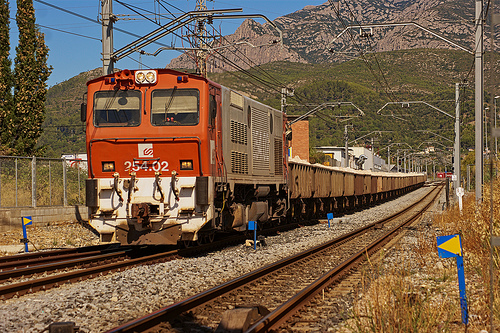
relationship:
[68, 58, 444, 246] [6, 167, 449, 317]
train on tracks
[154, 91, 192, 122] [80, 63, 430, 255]
part of a window of train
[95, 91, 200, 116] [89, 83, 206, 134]
blinds in windows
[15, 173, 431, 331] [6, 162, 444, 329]
rocks between tracks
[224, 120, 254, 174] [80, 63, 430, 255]
vents on side of train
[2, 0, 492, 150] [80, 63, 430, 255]
cables above train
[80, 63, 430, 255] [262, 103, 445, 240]
train on tracks side by side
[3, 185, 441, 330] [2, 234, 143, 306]
gravel between tracks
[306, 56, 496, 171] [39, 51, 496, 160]
hillside is covered in grass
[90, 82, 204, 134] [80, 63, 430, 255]
two windows on train